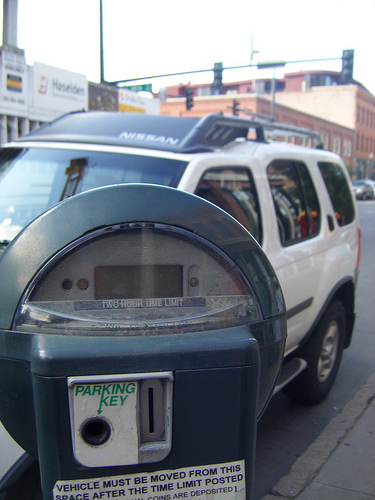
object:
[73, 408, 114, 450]
hole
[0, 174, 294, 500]
meter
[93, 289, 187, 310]
notification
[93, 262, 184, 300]
display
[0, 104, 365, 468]
vehicle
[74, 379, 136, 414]
letters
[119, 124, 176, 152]
nissan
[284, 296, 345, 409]
tire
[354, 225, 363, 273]
light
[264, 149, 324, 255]
window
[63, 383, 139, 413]
parking key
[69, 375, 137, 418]
words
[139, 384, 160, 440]
slot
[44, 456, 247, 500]
notice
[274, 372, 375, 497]
sidewalk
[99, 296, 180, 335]
sign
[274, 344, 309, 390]
step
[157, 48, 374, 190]
building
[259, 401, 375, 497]
road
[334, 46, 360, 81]
signals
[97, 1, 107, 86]
pole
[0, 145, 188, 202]
windshield